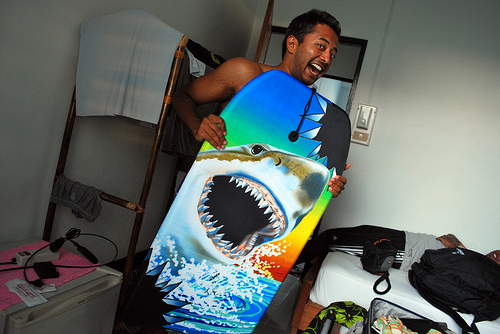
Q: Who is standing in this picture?
A: A man.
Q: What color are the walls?
A: White.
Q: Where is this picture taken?
A: In a bedroom.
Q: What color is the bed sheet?
A: White.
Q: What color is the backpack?
A: Black.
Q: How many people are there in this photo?
A: Two.